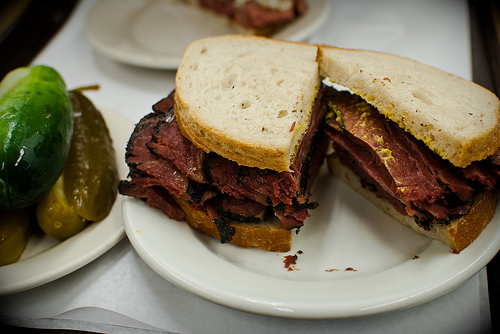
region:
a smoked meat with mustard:
[118, 33, 498, 251]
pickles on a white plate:
[0, 65, 127, 295]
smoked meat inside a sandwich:
[121, 88, 326, 240]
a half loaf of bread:
[171, 38, 319, 171]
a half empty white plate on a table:
[87, 2, 332, 65]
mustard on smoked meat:
[326, 92, 411, 193]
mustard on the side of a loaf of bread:
[355, 84, 448, 156]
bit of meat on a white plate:
[284, 251, 297, 270]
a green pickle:
[0, 61, 71, 216]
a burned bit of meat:
[214, 215, 235, 243]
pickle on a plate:
[67, 81, 113, 231]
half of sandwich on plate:
[125, 31, 320, 251]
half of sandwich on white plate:
[121, 30, 326, 260]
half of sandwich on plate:
[316, 32, 491, 249]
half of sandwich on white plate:
[320, 45, 495, 255]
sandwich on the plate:
[112, 35, 497, 315]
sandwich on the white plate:
[106, 12, 496, 317]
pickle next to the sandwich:
[65, 80, 115, 222]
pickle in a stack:
[51, 64, 118, 226]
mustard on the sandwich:
[338, 93, 396, 183]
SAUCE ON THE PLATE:
[283, 255, 296, 265]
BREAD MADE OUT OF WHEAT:
[420, 79, 447, 123]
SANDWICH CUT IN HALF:
[158, 48, 491, 245]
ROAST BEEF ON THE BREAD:
[407, 162, 413, 182]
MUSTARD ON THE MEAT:
[370, 130, 395, 145]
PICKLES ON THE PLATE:
[85, 155, 106, 210]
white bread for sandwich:
[151, 41, 478, 258]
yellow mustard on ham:
[331, 105, 428, 210]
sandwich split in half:
[157, 44, 457, 248]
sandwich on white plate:
[175, 62, 498, 290]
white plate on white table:
[177, 75, 473, 303]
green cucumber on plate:
[2, 57, 82, 205]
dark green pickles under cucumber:
[29, 79, 100, 277]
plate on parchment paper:
[75, 54, 485, 311]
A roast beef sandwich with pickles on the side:
[0, 22, 499, 287]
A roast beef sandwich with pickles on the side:
[2, 30, 495, 278]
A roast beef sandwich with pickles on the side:
[0, 30, 499, 298]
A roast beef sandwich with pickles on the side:
[0, 27, 496, 290]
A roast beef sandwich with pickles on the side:
[0, 26, 497, 276]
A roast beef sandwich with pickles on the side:
[0, 26, 497, 267]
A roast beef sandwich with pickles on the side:
[2, 30, 497, 266]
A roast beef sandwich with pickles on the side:
[2, 30, 499, 279]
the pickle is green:
[1, 62, 72, 207]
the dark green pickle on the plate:
[67, 88, 122, 223]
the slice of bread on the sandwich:
[177, 29, 323, 169]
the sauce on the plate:
[279, 246, 312, 278]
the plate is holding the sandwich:
[126, 172, 498, 319]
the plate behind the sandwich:
[84, 3, 330, 70]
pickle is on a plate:
[64, 86, 116, 216]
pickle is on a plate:
[38, 176, 83, 238]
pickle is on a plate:
[0, 207, 31, 264]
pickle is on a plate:
[2, 61, 72, 206]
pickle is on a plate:
[1, 68, 29, 95]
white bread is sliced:
[179, 37, 318, 168]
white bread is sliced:
[190, 209, 295, 251]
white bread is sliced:
[319, 44, 497, 167]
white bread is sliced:
[329, 155, 497, 252]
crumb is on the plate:
[284, 254, 298, 268]